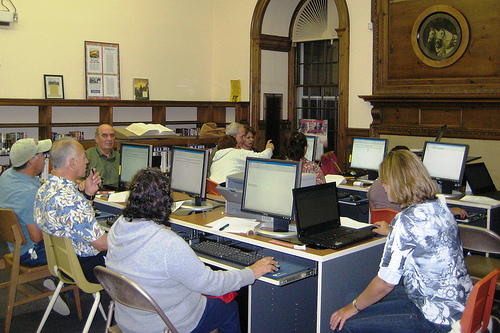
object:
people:
[102, 167, 277, 333]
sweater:
[103, 215, 254, 332]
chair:
[458, 268, 500, 332]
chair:
[33, 229, 100, 333]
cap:
[9, 138, 52, 168]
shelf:
[46, 104, 105, 125]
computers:
[240, 156, 298, 237]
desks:
[153, 199, 387, 333]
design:
[410, 4, 467, 68]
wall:
[383, 19, 498, 114]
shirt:
[80, 144, 125, 190]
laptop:
[292, 182, 378, 250]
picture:
[132, 78, 148, 101]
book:
[125, 123, 177, 137]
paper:
[230, 79, 242, 102]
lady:
[329, 149, 475, 333]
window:
[303, 47, 340, 113]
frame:
[410, 4, 474, 70]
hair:
[122, 167, 173, 225]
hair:
[378, 149, 436, 206]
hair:
[51, 139, 76, 167]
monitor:
[171, 148, 204, 194]